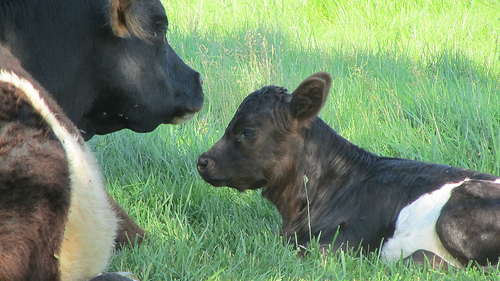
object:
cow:
[4, 5, 203, 280]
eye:
[142, 24, 162, 40]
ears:
[291, 67, 330, 118]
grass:
[174, 5, 494, 87]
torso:
[1, 54, 122, 279]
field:
[183, 8, 489, 161]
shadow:
[179, 23, 499, 172]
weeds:
[187, 12, 283, 65]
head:
[194, 87, 311, 190]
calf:
[194, 71, 498, 279]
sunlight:
[170, 4, 494, 68]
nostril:
[197, 158, 210, 172]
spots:
[377, 179, 469, 274]